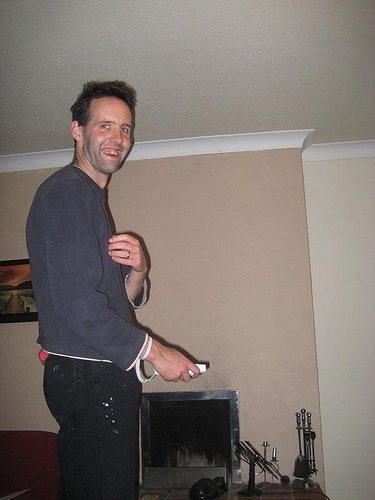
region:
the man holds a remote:
[157, 356, 209, 379]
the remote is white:
[157, 359, 207, 379]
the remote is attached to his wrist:
[139, 338, 208, 384]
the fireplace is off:
[142, 392, 241, 485]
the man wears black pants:
[46, 351, 144, 495]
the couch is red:
[1, 428, 62, 498]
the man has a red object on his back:
[40, 349, 44, 359]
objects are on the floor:
[226, 406, 324, 496]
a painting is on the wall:
[0, 258, 44, 322]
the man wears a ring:
[127, 250, 131, 259]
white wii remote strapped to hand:
[119, 323, 222, 402]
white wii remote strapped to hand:
[97, 311, 272, 432]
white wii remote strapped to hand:
[141, 335, 220, 381]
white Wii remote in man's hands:
[160, 355, 214, 377]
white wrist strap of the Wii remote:
[130, 327, 157, 381]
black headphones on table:
[185, 471, 232, 498]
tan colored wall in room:
[163, 163, 293, 341]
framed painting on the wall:
[2, 250, 49, 338]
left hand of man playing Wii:
[96, 225, 170, 279]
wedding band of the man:
[125, 250, 131, 261]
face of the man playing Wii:
[64, 67, 152, 190]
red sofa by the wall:
[0, 426, 64, 498]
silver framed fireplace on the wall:
[138, 384, 251, 494]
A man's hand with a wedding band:
[98, 226, 158, 301]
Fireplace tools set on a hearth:
[281, 400, 322, 493]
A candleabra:
[257, 430, 278, 460]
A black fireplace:
[137, 390, 244, 492]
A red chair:
[0, 414, 66, 495]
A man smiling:
[52, 75, 149, 210]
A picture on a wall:
[0, 250, 39, 321]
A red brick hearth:
[153, 483, 324, 495]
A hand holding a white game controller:
[142, 337, 211, 393]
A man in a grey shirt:
[24, 67, 185, 365]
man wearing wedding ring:
[110, 220, 179, 321]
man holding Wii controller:
[133, 301, 220, 404]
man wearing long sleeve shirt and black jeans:
[35, 76, 249, 451]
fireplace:
[141, 380, 262, 498]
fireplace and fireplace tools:
[139, 385, 336, 497]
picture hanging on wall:
[3, 248, 49, 345]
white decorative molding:
[147, 135, 372, 175]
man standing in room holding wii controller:
[33, 78, 243, 472]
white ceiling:
[64, 14, 354, 159]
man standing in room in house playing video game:
[22, 109, 304, 468]